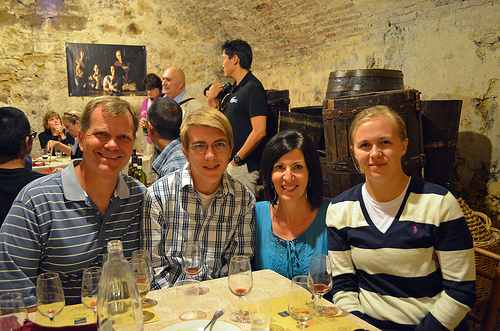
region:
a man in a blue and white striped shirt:
[0, 97, 147, 312]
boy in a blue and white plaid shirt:
[141, 107, 256, 290]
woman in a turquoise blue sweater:
[253, 130, 335, 277]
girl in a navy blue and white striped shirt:
[325, 106, 475, 329]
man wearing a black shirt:
[220, 39, 270, 199]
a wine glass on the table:
[35, 271, 65, 329]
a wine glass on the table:
[181, 240, 203, 296]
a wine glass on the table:
[225, 255, 253, 322]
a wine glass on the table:
[288, 276, 313, 328]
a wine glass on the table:
[307, 254, 333, 319]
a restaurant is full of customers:
[4, 10, 499, 326]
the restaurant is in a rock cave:
[5, 3, 499, 326]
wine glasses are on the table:
[29, 238, 332, 328]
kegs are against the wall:
[221, 68, 443, 230]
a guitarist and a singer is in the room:
[141, 33, 266, 161]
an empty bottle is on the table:
[85, 237, 150, 329]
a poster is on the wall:
[58, 35, 152, 97]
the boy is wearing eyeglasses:
[183, 132, 231, 156]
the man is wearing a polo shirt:
[15, 100, 145, 308]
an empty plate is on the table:
[167, 314, 247, 329]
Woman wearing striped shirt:
[323, 105, 476, 329]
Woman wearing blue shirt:
[248, 128, 335, 290]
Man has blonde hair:
[145, 105, 255, 285]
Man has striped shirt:
[0, 98, 155, 310]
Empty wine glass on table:
[227, 254, 254, 321]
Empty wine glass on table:
[285, 274, 318, 329]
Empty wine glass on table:
[34, 270, 66, 327]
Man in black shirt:
[206, 38, 268, 199]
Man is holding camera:
[199, 37, 271, 192]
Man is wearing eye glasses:
[140, 113, 252, 288]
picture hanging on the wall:
[65, 43, 147, 95]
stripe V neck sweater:
[325, 178, 475, 325]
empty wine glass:
[225, 256, 252, 318]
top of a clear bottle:
[100, 238, 142, 327]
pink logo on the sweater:
[411, 226, 421, 234]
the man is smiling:
[74, 98, 139, 195]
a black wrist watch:
[232, 155, 241, 162]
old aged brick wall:
[5, 1, 497, 208]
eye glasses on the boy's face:
[187, 138, 233, 152]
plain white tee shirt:
[360, 185, 412, 232]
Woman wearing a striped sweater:
[305, 102, 473, 329]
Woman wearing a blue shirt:
[230, 124, 337, 289]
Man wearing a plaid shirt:
[144, 106, 265, 287]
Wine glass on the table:
[218, 250, 260, 329]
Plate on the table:
[157, 307, 251, 329]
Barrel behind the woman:
[310, 48, 456, 214]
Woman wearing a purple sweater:
[130, 69, 167, 144]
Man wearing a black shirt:
[198, 36, 280, 203]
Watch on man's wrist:
[224, 150, 247, 171]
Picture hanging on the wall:
[53, 26, 153, 106]